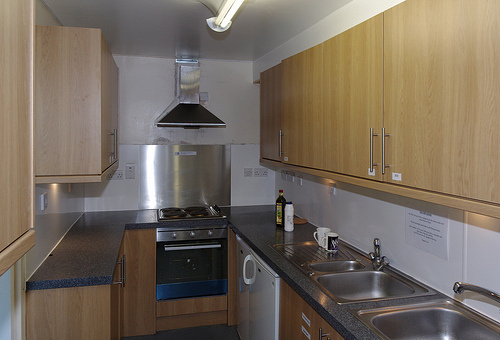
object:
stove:
[156, 204, 232, 302]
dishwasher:
[232, 235, 280, 339]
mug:
[313, 227, 332, 247]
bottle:
[274, 186, 284, 230]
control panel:
[155, 224, 228, 242]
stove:
[157, 204, 227, 221]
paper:
[404, 206, 452, 261]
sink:
[357, 300, 498, 338]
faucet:
[453, 279, 499, 306]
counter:
[24, 205, 162, 293]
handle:
[379, 126, 388, 174]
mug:
[312, 225, 338, 254]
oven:
[152, 220, 231, 301]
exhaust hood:
[156, 59, 228, 129]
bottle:
[284, 201, 295, 232]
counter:
[224, 204, 498, 338]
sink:
[309, 259, 367, 273]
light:
[204, 0, 249, 33]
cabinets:
[255, 4, 498, 222]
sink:
[313, 263, 431, 305]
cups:
[322, 233, 339, 252]